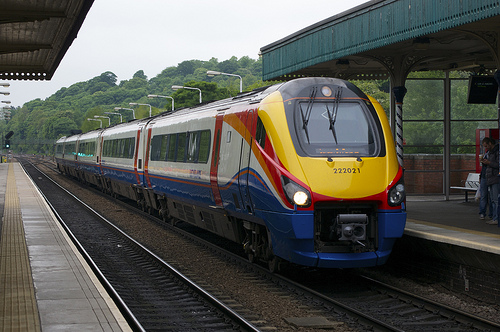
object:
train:
[54, 77, 411, 267]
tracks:
[183, 278, 376, 332]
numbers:
[332, 168, 360, 174]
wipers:
[300, 86, 345, 144]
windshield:
[289, 98, 381, 155]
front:
[262, 77, 410, 270]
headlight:
[292, 190, 311, 207]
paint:
[295, 215, 310, 239]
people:
[477, 135, 498, 228]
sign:
[468, 75, 498, 105]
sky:
[149, 5, 208, 40]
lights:
[146, 70, 222, 101]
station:
[259, 0, 500, 255]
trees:
[78, 67, 153, 91]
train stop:
[389, 23, 499, 242]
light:
[6, 144, 10, 148]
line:
[443, 224, 474, 236]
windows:
[149, 129, 210, 163]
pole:
[389, 83, 405, 167]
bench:
[450, 173, 480, 203]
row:
[148, 85, 201, 98]